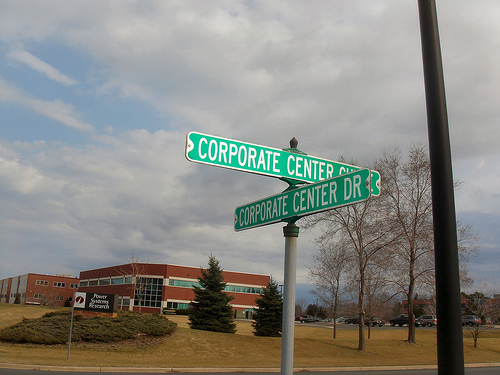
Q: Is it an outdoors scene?
A: Yes, it is outdoors.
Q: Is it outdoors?
A: Yes, it is outdoors.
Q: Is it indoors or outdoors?
A: It is outdoors.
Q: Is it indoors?
A: No, it is outdoors.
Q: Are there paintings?
A: No, there are no paintings.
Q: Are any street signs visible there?
A: Yes, there is a street sign.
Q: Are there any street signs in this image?
A: Yes, there is a street sign.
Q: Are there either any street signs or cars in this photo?
A: Yes, there is a street sign.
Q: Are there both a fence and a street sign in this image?
A: No, there is a street sign but no fences.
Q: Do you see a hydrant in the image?
A: No, there are no fire hydrants.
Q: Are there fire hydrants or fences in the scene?
A: No, there are no fire hydrants or fences.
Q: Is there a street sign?
A: Yes, there is a street sign.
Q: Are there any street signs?
A: Yes, there is a street sign.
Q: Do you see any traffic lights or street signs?
A: Yes, there is a street sign.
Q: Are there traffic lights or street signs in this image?
A: Yes, there is a street sign.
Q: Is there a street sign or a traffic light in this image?
A: Yes, there is a street sign.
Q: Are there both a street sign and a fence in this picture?
A: No, there is a street sign but no fences.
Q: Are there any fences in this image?
A: No, there are no fences.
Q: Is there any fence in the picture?
A: No, there are no fences.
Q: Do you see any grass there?
A: Yes, there is grass.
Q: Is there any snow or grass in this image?
A: Yes, there is grass.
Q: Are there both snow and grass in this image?
A: No, there is grass but no snow.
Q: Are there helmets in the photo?
A: No, there are no helmets.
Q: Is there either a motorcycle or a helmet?
A: No, there are no helmets or motorcycles.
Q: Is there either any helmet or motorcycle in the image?
A: No, there are no helmets or motorcycles.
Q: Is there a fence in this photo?
A: No, there are no fences.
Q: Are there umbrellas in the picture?
A: No, there are no umbrellas.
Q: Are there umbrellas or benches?
A: No, there are no umbrellas or benches.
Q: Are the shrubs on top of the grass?
A: Yes, the shrubs are on top of the grass.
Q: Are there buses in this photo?
A: No, there are no buses.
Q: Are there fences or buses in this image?
A: No, there are no buses or fences.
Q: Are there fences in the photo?
A: No, there are no fences.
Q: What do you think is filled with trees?
A: The forest is filled with trees.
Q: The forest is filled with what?
A: The forest is filled with trees.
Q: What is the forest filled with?
A: The forest is filled with trees.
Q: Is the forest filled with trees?
A: Yes, the forest is filled with trees.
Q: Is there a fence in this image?
A: No, there are no fences.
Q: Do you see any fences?
A: No, there are no fences.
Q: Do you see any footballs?
A: No, there are no footballs.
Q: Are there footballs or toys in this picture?
A: No, there are no footballs or toys.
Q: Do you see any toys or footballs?
A: No, there are no footballs or toys.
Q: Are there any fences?
A: No, there are no fences.